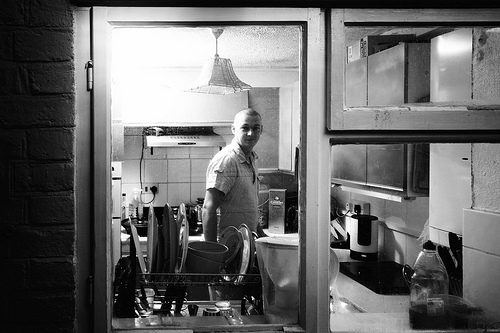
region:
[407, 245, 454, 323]
GLASS BOTTLE ON THE COUNTER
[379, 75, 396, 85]
CABINETS MADE OUT OF WOOD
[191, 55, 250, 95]
LIGHT HANGING FROM THE CEILING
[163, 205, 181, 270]
PLATES IN THE DRAINER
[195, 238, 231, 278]
POT IN THE DRAINER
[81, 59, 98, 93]
HINGES ON THE WINDOW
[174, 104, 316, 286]
this is a man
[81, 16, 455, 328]
this is a kitchen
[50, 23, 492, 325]
this is a window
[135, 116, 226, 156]
this is a vent hood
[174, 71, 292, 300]
man looking out window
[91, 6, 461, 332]
man standing in kitchen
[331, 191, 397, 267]
this is a kettle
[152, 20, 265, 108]
this is a light fixture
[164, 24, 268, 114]
light attached to ceiling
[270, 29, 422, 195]
a set of cabinets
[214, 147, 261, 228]
A shirt in the photo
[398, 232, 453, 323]
A bottle on the table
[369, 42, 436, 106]
Glass panes in the photo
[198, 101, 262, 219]
A man in the house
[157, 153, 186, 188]
Tiles in the photo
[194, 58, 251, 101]
A lighting on the ceiling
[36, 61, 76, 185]
A stone wall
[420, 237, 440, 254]
A black cap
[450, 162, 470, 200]
A tile on the wall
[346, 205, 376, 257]
A blender in the kitchen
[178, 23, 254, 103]
light hanging from ceiling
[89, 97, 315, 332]
man standing in kitchen looking out of the window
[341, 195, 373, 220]
white wall outlet in kitchen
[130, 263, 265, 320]
drying dish rack on countertop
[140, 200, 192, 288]
plates stacked vertically in dish rack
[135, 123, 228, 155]
ventilation hood above stove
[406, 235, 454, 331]
white clear bottle on counter top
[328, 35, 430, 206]
cabinets above countertop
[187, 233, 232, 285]
bucket in dish rack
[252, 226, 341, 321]
container on countertop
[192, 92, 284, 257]
A man standing in the kitchen.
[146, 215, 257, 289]
Dishes on the rack.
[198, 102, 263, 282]
man in a kitchen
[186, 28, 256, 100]
light fixture hanging from the ceiling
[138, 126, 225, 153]
light under a cabinet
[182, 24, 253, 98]
Light hanging from a ceiling over a man.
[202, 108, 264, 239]
Man looking out of the window.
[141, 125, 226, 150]
White vent hood above a stove.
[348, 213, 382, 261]
Black and white cylinder on the counter.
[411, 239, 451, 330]
Clear plastic bottle with liquid on a window sill.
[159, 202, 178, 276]
Dark plate in between two light plates on a rack.